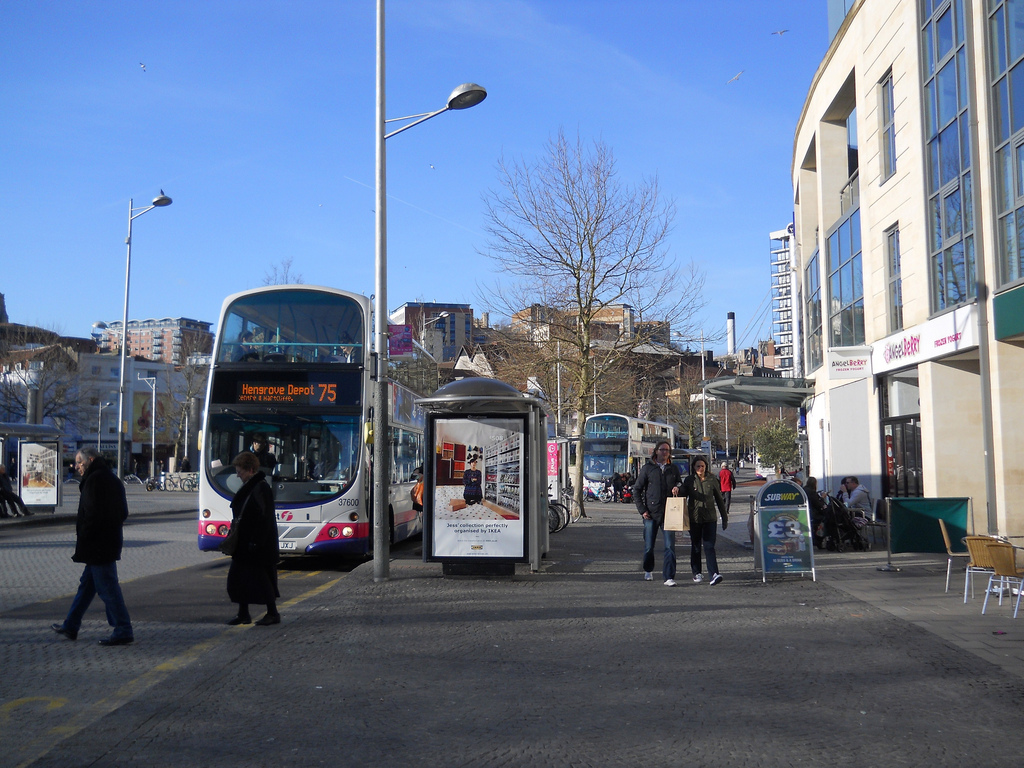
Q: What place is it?
A: It is a street.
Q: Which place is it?
A: It is a street.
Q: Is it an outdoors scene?
A: Yes, it is outdoors.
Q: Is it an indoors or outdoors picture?
A: It is outdoors.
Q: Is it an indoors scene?
A: No, it is outdoors.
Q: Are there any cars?
A: No, there are no cars.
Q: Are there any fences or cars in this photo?
A: No, there are no cars or fences.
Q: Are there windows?
A: Yes, there is a window.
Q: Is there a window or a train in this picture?
A: Yes, there is a window.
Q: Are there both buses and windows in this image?
A: Yes, there are both a window and a bus.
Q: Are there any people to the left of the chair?
A: Yes, there are people to the left of the chair.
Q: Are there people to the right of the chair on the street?
A: No, the people are to the left of the chair.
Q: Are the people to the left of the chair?
A: Yes, the people are to the left of the chair.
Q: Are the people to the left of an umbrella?
A: No, the people are to the left of the chair.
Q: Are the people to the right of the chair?
A: No, the people are to the left of the chair.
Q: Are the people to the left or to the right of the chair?
A: The people are to the left of the chair.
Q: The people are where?
A: The people are on the street.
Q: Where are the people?
A: The people are on the street.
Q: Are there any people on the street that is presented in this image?
A: Yes, there are people on the street.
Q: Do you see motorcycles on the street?
A: No, there are people on the street.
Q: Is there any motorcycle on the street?
A: No, there are people on the street.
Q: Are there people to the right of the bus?
A: Yes, there are people to the right of the bus.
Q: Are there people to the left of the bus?
A: No, the people are to the right of the bus.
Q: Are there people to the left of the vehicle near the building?
A: No, the people are to the right of the bus.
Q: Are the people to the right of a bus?
A: Yes, the people are to the right of a bus.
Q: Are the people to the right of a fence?
A: No, the people are to the right of a bus.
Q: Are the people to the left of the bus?
A: No, the people are to the right of the bus.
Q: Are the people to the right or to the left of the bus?
A: The people are to the right of the bus.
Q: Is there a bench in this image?
A: No, there are no benches.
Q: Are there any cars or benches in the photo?
A: No, there are no benches or cars.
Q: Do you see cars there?
A: No, there are no cars.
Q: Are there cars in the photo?
A: No, there are no cars.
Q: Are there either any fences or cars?
A: No, there are no cars or fences.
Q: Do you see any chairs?
A: Yes, there is a chair.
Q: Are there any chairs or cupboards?
A: Yes, there is a chair.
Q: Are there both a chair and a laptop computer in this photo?
A: No, there is a chair but no laptops.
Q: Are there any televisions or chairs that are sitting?
A: Yes, the chair is sitting.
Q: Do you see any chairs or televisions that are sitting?
A: Yes, the chair is sitting.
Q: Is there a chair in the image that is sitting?
A: Yes, there is a chair that is sitting.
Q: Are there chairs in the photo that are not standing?
A: Yes, there is a chair that is sitting.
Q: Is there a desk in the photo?
A: No, there are no desks.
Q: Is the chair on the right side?
A: Yes, the chair is on the right of the image.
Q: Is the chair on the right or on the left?
A: The chair is on the right of the image.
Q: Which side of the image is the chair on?
A: The chair is on the right of the image.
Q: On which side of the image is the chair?
A: The chair is on the right of the image.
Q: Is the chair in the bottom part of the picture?
A: Yes, the chair is in the bottom of the image.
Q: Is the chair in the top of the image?
A: No, the chair is in the bottom of the image.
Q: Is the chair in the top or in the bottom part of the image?
A: The chair is in the bottom of the image.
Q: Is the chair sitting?
A: Yes, the chair is sitting.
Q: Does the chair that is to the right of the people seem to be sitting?
A: Yes, the chair is sitting.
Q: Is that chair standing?
A: No, the chair is sitting.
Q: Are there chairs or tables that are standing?
A: No, there is a chair but it is sitting.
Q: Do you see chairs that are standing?
A: No, there is a chair but it is sitting.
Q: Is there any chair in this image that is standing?
A: No, there is a chair but it is sitting.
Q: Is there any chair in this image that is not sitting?
A: No, there is a chair but it is sitting.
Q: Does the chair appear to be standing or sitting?
A: The chair is sitting.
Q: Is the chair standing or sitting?
A: The chair is sitting.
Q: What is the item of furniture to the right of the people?
A: The piece of furniture is a chair.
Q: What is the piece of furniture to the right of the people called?
A: The piece of furniture is a chair.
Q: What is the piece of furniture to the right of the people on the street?
A: The piece of furniture is a chair.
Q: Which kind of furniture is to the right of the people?
A: The piece of furniture is a chair.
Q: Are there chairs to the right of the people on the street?
A: Yes, there is a chair to the right of the people.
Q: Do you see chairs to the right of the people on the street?
A: Yes, there is a chair to the right of the people.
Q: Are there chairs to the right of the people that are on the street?
A: Yes, there is a chair to the right of the people.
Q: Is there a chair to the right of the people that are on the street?
A: Yes, there is a chair to the right of the people.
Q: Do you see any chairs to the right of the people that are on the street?
A: Yes, there is a chair to the right of the people.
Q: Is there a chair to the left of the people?
A: No, the chair is to the right of the people.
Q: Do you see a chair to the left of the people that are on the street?
A: No, the chair is to the right of the people.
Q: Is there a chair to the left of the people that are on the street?
A: No, the chair is to the right of the people.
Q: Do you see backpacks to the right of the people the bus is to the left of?
A: No, there is a chair to the right of the people.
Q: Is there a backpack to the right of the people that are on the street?
A: No, there is a chair to the right of the people.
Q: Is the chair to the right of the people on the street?
A: Yes, the chair is to the right of the people.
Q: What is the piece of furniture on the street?
A: The piece of furniture is a chair.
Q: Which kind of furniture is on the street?
A: The piece of furniture is a chair.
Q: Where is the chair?
A: The chair is on the street.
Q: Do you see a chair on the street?
A: Yes, there is a chair on the street.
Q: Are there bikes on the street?
A: No, there is a chair on the street.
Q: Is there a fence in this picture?
A: No, there are no fences.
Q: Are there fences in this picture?
A: No, there are no fences.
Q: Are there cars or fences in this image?
A: No, there are no fences or cars.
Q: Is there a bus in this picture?
A: Yes, there is a bus.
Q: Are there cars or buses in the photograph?
A: Yes, there is a bus.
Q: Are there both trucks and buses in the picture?
A: No, there is a bus but no trucks.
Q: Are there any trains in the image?
A: No, there are no trains.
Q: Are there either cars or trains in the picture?
A: No, there are no trains or cars.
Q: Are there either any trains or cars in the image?
A: No, there are no trains or cars.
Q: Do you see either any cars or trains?
A: No, there are no trains or cars.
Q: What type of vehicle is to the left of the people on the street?
A: The vehicle is a bus.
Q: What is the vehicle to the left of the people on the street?
A: The vehicle is a bus.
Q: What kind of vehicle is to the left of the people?
A: The vehicle is a bus.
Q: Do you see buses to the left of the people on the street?
A: Yes, there is a bus to the left of the people.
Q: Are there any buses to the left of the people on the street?
A: Yes, there is a bus to the left of the people.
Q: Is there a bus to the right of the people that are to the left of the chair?
A: No, the bus is to the left of the people.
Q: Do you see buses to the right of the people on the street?
A: No, the bus is to the left of the people.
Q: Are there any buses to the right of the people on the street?
A: No, the bus is to the left of the people.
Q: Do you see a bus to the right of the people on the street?
A: No, the bus is to the left of the people.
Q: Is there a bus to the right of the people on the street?
A: No, the bus is to the left of the people.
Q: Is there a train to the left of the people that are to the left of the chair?
A: No, there is a bus to the left of the people.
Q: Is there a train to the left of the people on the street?
A: No, there is a bus to the left of the people.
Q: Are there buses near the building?
A: Yes, there is a bus near the building.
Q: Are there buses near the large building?
A: Yes, there is a bus near the building.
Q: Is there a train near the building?
A: No, there is a bus near the building.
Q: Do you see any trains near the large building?
A: No, there is a bus near the building.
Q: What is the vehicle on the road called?
A: The vehicle is a bus.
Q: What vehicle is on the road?
A: The vehicle is a bus.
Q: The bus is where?
A: The bus is on the road.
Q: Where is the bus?
A: The bus is on the road.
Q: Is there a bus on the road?
A: Yes, there is a bus on the road.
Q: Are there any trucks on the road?
A: No, there is a bus on the road.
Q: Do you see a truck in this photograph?
A: No, there are no trucks.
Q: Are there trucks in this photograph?
A: No, there are no trucks.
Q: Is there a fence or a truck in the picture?
A: No, there are no trucks or fences.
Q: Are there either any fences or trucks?
A: No, there are no trucks or fences.